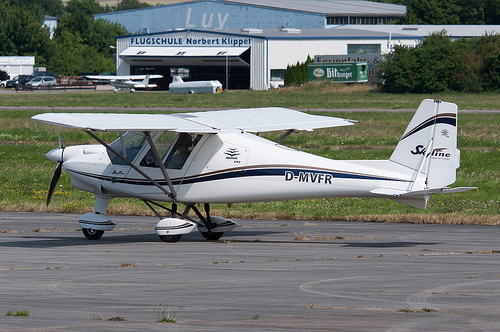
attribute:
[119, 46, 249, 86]
door — wide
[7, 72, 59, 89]
cars — parked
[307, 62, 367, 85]
green trailer — green 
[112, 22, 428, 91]
airplane hanger — white 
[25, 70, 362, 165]
wings — rectangular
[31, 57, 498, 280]
aircraft — white, small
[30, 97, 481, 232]
plane — small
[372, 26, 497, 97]
bushes — green